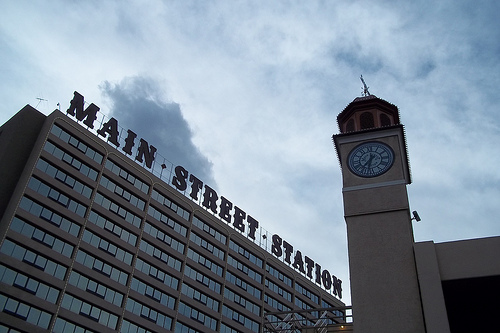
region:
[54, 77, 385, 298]
sign says Main Street Station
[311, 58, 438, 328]
large clock in a tower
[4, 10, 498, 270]
clouds in the sky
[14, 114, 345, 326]
building has many windows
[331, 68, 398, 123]
weather vane on the top of the tower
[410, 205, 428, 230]
security camera on the side of the tower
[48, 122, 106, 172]
each window has six sections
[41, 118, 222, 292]
windows and narrow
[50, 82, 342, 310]
main street ststion font is old fashioned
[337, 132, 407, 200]
clock reads 6:35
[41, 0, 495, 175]
Sky Looks like a Storm is coming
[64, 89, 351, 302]
This is the Main Street Station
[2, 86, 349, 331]
Building has several floors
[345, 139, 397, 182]
Clock shows a little past 7:30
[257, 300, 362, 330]
Walk out Balcony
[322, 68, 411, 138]
The View is good from up heere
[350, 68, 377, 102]
Lookout Tower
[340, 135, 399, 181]
the Clock is Blue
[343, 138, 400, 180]
The clock is outlined in black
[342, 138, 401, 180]
the Clock has roman numerals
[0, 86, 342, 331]
Main Street Station center.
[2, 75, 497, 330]
Main Street Station building.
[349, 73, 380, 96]
Statue on top of building.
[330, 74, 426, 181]
Clock on side of a building.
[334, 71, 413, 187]
Statue above a clock on building.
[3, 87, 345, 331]
Train station next to building with clock.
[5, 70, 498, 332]
Building with statue next to Main Street Station.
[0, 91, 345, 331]
Windows on the side of Main Street Station.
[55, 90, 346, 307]
Sign that reads Main Street Station.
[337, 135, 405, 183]
Clock with roman numerals on side of building.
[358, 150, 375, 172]
the hands of a clock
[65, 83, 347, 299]
large letters above a building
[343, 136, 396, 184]
a round clock face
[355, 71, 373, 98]
a weather vane on the building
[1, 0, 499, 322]
a cloudy blue sky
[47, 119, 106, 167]
a row of windows on a building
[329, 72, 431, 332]
a clock tower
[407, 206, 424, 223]
a camera on the building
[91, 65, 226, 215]
smoke in the sky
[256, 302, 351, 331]
a railing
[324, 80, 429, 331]
a building's clock tower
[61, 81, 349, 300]
the name of a building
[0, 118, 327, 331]
a large building with many windows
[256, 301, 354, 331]
hand rails by stairs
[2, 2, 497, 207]
a white and gray cloudy sky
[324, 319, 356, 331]
a light on a wall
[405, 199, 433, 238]
a security camera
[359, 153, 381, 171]
the two hands on a clock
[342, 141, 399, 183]
a clock using Roman Numeral numbers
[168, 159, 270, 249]
a sign that says street